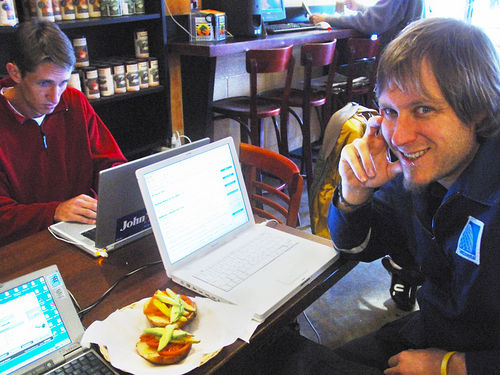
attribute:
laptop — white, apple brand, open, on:
[134, 135, 344, 322]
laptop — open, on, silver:
[0, 263, 120, 374]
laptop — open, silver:
[48, 136, 210, 259]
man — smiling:
[327, 17, 498, 373]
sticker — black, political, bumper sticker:
[116, 210, 151, 239]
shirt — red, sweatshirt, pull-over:
[0, 78, 123, 243]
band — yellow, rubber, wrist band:
[438, 350, 460, 373]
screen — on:
[144, 144, 249, 265]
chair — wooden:
[237, 141, 305, 230]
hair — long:
[375, 17, 500, 142]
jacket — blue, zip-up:
[329, 137, 500, 374]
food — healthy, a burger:
[137, 288, 198, 366]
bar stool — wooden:
[213, 44, 295, 158]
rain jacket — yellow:
[313, 103, 372, 242]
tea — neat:
[1, 0, 160, 28]